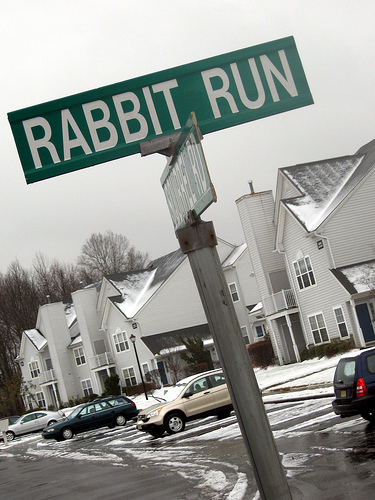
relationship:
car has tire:
[40, 395, 139, 441] [60, 427, 77, 438]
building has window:
[227, 138, 374, 368] [288, 253, 318, 293]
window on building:
[288, 253, 318, 293] [227, 138, 374, 368]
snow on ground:
[1, 434, 354, 500] [3, 346, 374, 498]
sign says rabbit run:
[5, 35, 316, 186] [24, 47, 299, 170]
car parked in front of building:
[40, 395, 139, 441] [227, 138, 374, 368]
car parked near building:
[40, 395, 139, 441] [227, 138, 374, 368]